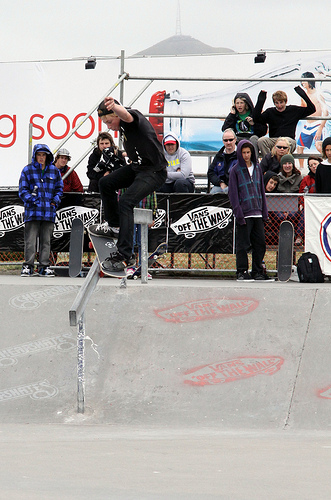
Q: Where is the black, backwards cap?
A: On the skateboarder.